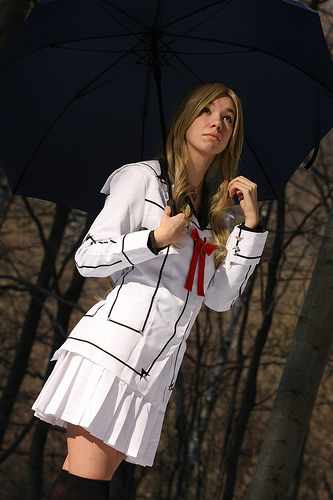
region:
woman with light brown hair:
[141, 71, 261, 224]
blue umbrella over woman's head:
[36, 12, 320, 160]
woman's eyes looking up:
[193, 97, 240, 127]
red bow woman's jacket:
[181, 222, 214, 300]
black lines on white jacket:
[99, 304, 157, 373]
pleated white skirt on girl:
[35, 348, 172, 461]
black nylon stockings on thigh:
[34, 458, 122, 497]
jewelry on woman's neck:
[177, 176, 205, 204]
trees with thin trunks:
[188, 346, 267, 452]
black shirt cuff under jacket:
[237, 221, 268, 237]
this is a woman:
[43, 77, 238, 494]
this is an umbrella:
[39, 2, 94, 198]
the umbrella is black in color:
[22, 59, 48, 114]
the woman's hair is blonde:
[177, 92, 194, 119]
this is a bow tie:
[190, 239, 211, 298]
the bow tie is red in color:
[197, 239, 208, 252]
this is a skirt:
[76, 373, 113, 429]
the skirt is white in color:
[60, 373, 101, 418]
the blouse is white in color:
[120, 184, 142, 360]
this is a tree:
[282, 179, 332, 498]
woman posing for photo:
[28, 84, 274, 451]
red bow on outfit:
[178, 229, 218, 301]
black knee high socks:
[40, 465, 121, 498]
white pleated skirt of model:
[27, 343, 183, 473]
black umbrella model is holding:
[6, 2, 332, 77]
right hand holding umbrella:
[146, 198, 194, 248]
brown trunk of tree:
[235, 251, 332, 494]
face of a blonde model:
[165, 73, 248, 183]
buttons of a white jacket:
[231, 233, 245, 262]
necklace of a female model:
[184, 174, 210, 208]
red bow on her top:
[177, 226, 225, 294]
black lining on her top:
[77, 156, 197, 402]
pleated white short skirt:
[30, 347, 197, 464]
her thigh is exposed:
[39, 413, 141, 491]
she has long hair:
[173, 83, 279, 249]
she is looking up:
[180, 80, 256, 180]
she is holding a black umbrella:
[127, 51, 297, 286]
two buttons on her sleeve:
[220, 225, 261, 265]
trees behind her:
[176, 303, 331, 437]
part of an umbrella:
[253, 59, 291, 98]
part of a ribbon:
[183, 255, 211, 296]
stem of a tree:
[267, 416, 299, 490]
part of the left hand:
[235, 181, 258, 227]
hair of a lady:
[171, 136, 196, 176]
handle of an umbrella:
[161, 181, 177, 207]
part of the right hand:
[161, 216, 183, 236]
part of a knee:
[89, 447, 117, 466]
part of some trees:
[186, 381, 234, 465]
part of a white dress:
[93, 400, 149, 458]